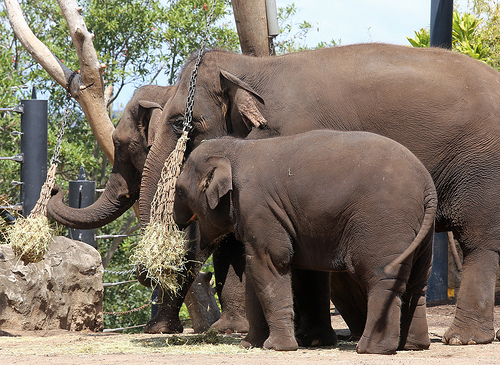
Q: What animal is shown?
A: Elephant.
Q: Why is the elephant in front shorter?
A: Younger.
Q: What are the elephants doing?
A: Eating.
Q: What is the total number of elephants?
A: 3.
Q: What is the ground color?
A: Brown.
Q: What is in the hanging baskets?
A: Hay.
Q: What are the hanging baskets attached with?
A: Chain.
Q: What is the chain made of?
A: Metal.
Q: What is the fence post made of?
A: Metal.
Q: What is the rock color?
A: Brown.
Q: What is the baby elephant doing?
A: Eating hay.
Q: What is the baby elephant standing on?
A: Four legs.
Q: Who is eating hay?
A: A family of elephants.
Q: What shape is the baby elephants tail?
A: It's curved.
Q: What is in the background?
A: Tall trees.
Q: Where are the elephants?
A: In an enclosure.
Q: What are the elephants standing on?
A: Dirt.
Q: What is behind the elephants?
A: A fence.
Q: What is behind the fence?
A: Trees.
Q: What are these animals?
A: Elephants.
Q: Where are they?
A: A zoo or refuge.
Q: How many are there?
A: 3.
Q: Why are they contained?
A: Protection and viewing.